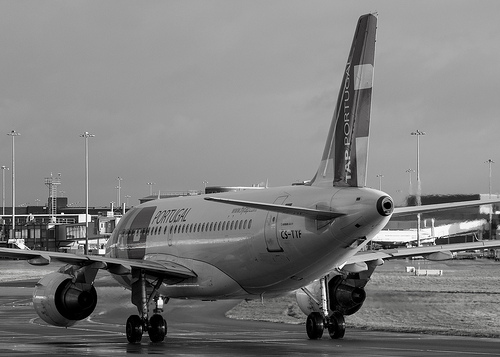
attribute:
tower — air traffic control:
[43, 170, 62, 214]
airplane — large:
[0, 13, 500, 344]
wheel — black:
[126, 316, 142, 344]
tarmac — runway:
[1, 270, 498, 356]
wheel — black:
[329, 313, 345, 340]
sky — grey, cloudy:
[0, 0, 499, 206]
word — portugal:
[150, 207, 191, 223]